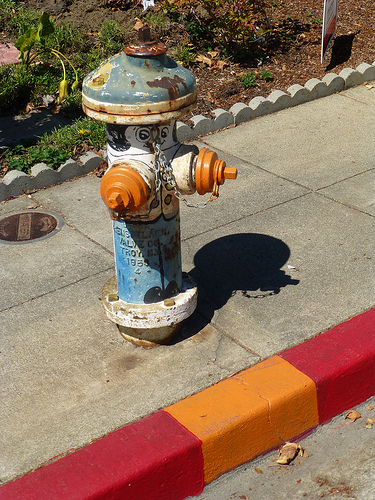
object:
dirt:
[24, 0, 375, 129]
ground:
[0, 0, 374, 499]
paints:
[111, 431, 150, 488]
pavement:
[190, 395, 375, 499]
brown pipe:
[1, 209, 58, 241]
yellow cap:
[192, 145, 240, 196]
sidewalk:
[0, 60, 375, 498]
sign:
[320, 0, 331, 63]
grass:
[0, 2, 124, 180]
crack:
[229, 371, 272, 424]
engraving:
[118, 226, 160, 277]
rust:
[130, 21, 165, 55]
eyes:
[138, 129, 150, 141]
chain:
[154, 143, 218, 211]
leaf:
[273, 439, 309, 467]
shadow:
[145, 222, 303, 348]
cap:
[81, 49, 196, 104]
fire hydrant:
[81, 16, 239, 348]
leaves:
[343, 406, 362, 423]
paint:
[308, 347, 339, 370]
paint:
[222, 389, 241, 405]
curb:
[3, 307, 375, 497]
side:
[100, 158, 151, 223]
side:
[196, 139, 242, 199]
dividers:
[171, 63, 375, 145]